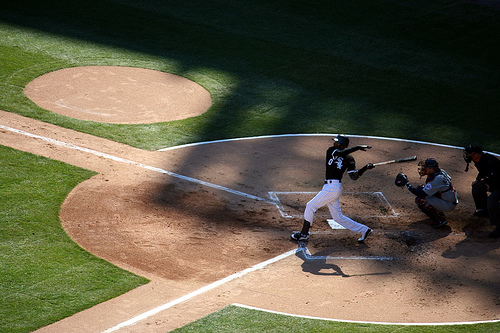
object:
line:
[117, 156, 257, 203]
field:
[233, 65, 378, 137]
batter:
[290, 133, 375, 245]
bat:
[366, 155, 418, 169]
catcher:
[394, 157, 459, 227]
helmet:
[331, 136, 350, 148]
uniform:
[422, 169, 460, 213]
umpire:
[461, 141, 499, 240]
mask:
[417, 159, 426, 179]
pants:
[300, 179, 373, 235]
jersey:
[325, 146, 374, 180]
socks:
[301, 219, 312, 234]